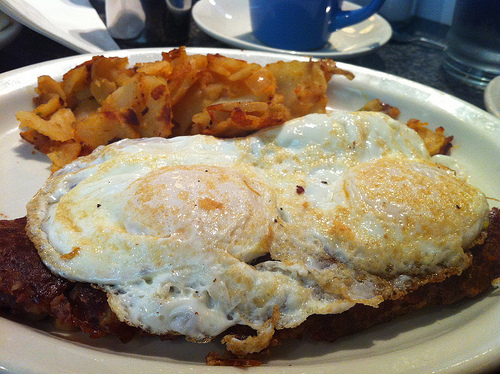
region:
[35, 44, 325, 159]
brown potatoes on plate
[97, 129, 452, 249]
two eggs on meat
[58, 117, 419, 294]
two fried eggs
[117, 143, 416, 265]
two eggs have yellow yolks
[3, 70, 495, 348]
plate is white and ovular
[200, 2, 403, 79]
white saucer behind plate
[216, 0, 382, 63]
blue mug on saucer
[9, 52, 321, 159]
orange fried potatoes on plate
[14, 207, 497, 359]
meat is dark brown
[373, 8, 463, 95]
table is dark grey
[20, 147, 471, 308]
two fried eggs on a plate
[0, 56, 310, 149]
fried potatoes on a plate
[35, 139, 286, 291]
a fried egg on a plate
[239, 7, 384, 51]
a blue coffee cup on saucer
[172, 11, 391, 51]
a white saucer on a table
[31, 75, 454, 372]
a white plate on a table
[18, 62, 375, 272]
fried eggs and fried potatoes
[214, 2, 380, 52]
a cup and saucer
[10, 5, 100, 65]
a white napkin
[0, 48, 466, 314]
food on a white plate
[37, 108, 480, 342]
There are two eggs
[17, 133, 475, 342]
Two over easy eggs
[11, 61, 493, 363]
Breakfast meal on plate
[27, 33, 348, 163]
Home fries on plate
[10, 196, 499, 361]
Piece of meat under the eggs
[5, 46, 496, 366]
White ceramic plate on table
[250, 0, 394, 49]
This is a blue coffee mug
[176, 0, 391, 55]
Small ceramic plate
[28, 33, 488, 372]
This is a plate of breakfast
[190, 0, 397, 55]
Coffee mug on saucer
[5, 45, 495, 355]
White plate of food.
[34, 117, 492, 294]
Two cooked eggs.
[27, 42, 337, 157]
Pile of hash browns on plate.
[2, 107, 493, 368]
Eggs on top of a piece of meat.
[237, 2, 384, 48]
Blue coffee cup.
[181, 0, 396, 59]
White round saucer with cup on it.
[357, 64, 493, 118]
Light shining on edge of plate.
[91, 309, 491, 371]
Shadow of meat on plate.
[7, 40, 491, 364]
Plate of breakfast food.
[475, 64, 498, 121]
White dish next to plate of food.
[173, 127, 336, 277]
this is some fried eggs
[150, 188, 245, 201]
this is a yolk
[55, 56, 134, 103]
this is a bunch of potatoes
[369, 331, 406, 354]
this is a plate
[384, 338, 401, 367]
the plate is white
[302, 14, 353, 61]
this is a mug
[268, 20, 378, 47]
the mug is blue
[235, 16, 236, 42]
this is a saucer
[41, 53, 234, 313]
this is a breakfast plate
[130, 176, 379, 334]
there are no people